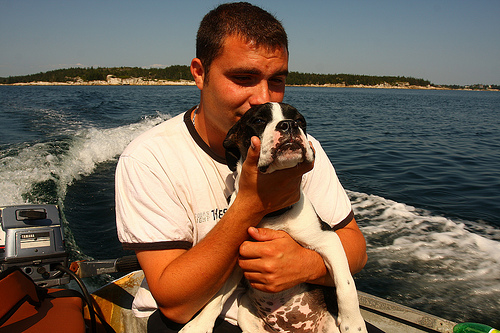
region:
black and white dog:
[214, 110, 321, 202]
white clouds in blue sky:
[370, 29, 392, 59]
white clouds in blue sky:
[411, 19, 454, 49]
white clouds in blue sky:
[329, 34, 356, 61]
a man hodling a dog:
[167, 48, 389, 325]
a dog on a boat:
[194, 65, 349, 322]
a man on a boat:
[110, 18, 420, 305]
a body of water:
[364, 90, 484, 217]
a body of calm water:
[351, 105, 486, 197]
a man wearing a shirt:
[154, 42, 324, 284]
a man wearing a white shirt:
[99, 28, 368, 332]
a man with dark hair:
[202, 1, 310, 158]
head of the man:
[176, 12, 333, 119]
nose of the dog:
[272, 113, 309, 138]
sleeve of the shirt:
[101, 153, 203, 250]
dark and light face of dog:
[225, 84, 335, 180]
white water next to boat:
[404, 213, 481, 270]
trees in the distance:
[25, 48, 155, 95]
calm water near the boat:
[382, 93, 472, 153]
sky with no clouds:
[29, 8, 161, 60]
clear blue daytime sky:
[0, 0, 498, 81]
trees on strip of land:
[0, 60, 497, 85]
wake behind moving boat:
[0, 111, 168, 203]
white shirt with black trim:
[112, 106, 354, 312]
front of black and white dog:
[187, 103, 367, 331]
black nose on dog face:
[228, 100, 313, 170]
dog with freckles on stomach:
[183, 100, 364, 330]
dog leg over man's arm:
[241, 225, 368, 332]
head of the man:
[161, 15, 325, 117]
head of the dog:
[215, 98, 327, 184]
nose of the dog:
[263, 110, 307, 150]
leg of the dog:
[296, 225, 373, 332]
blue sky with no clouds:
[20, 3, 135, 55]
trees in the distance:
[44, 50, 165, 91]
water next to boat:
[393, 169, 481, 253]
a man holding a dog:
[169, 15, 382, 311]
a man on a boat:
[154, 5, 423, 304]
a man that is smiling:
[198, 15, 278, 122]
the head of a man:
[175, 9, 307, 147]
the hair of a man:
[224, 6, 292, 66]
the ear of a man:
[171, 49, 221, 101]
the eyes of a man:
[218, 61, 290, 95]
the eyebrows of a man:
[231, 61, 292, 85]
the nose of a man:
[240, 73, 274, 114]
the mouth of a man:
[222, 98, 256, 128]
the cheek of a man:
[215, 81, 253, 116]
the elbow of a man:
[145, 248, 200, 332]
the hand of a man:
[224, 212, 315, 317]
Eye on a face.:
[252, 114, 265, 125]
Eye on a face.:
[293, 117, 308, 122]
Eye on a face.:
[228, 73, 259, 90]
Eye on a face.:
[271, 76, 288, 85]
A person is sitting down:
[111, 15, 368, 331]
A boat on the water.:
[22, 239, 480, 331]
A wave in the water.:
[54, 128, 77, 223]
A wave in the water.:
[49, 103, 171, 156]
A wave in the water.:
[388, 212, 486, 299]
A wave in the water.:
[333, 185, 488, 307]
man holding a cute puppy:
[110, 4, 367, 331]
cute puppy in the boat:
[195, 100, 362, 332]